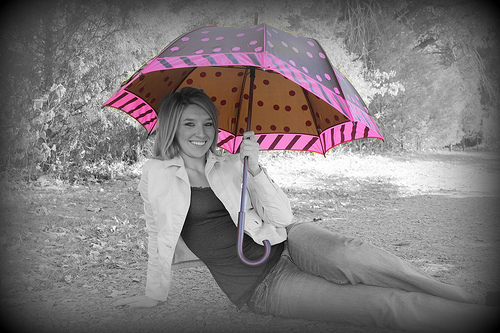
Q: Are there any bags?
A: No, there are no bags.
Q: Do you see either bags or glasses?
A: No, there are no bags or glasses.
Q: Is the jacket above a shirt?
A: Yes, the jacket is above a shirt.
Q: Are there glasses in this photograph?
A: No, there are no glasses.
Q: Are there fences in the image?
A: No, there are no fences.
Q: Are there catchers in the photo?
A: No, there are no catchers.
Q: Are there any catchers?
A: No, there are no catchers.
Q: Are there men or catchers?
A: No, there are no catchers or men.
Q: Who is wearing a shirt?
A: The girl is wearing a shirt.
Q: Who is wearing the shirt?
A: The girl is wearing a shirt.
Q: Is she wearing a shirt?
A: Yes, the girl is wearing a shirt.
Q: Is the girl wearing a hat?
A: No, the girl is wearing a shirt.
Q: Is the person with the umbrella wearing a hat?
A: No, the girl is wearing a shirt.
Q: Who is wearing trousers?
A: The girl is wearing trousers.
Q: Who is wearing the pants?
A: The girl is wearing trousers.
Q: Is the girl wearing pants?
A: Yes, the girl is wearing pants.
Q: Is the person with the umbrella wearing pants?
A: Yes, the girl is wearing pants.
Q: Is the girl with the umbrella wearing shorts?
A: No, the girl is wearing pants.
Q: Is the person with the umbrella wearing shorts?
A: No, the girl is wearing pants.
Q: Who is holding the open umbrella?
A: The girl is holding the umbrella.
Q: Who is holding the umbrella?
A: The girl is holding the umbrella.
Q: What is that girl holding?
A: The girl is holding the umbrella.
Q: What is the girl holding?
A: The girl is holding the umbrella.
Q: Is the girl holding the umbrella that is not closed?
A: Yes, the girl is holding the umbrella.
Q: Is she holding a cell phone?
A: No, the girl is holding the umbrella.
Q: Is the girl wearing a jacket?
A: Yes, the girl is wearing a jacket.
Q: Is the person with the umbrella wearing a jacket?
A: Yes, the girl is wearing a jacket.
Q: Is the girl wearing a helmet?
A: No, the girl is wearing a jacket.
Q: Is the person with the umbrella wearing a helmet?
A: No, the girl is wearing a jacket.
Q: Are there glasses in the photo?
A: No, there are no glasses.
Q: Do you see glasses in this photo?
A: No, there are no glasses.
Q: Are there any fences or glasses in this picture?
A: No, there are no glasses or fences.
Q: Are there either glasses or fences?
A: No, there are no glasses or fences.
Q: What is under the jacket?
A: The shirt is under the jacket.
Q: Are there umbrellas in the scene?
A: Yes, there is an umbrella.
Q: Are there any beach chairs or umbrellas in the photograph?
A: Yes, there is an umbrella.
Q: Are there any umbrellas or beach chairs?
A: Yes, there is an umbrella.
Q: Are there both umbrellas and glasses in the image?
A: No, there is an umbrella but no glasses.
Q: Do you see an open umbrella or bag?
A: Yes, there is an open umbrella.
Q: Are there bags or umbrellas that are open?
A: Yes, the umbrella is open.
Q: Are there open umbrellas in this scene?
A: Yes, there is an open umbrella.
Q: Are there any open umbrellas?
A: Yes, there is an open umbrella.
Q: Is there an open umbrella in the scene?
A: Yes, there is an open umbrella.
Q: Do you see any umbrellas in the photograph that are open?
A: Yes, there is an umbrella that is open.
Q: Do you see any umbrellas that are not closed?
A: Yes, there is a open umbrella.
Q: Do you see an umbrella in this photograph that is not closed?
A: Yes, there is a open umbrella.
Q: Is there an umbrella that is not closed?
A: Yes, there is a open umbrella.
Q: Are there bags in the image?
A: No, there are no bags.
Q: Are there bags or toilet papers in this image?
A: No, there are no bags or toilet papers.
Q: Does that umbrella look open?
A: Yes, the umbrella is open.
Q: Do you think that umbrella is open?
A: Yes, the umbrella is open.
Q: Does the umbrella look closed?
A: No, the umbrella is open.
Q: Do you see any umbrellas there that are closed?
A: No, there is an umbrella but it is open.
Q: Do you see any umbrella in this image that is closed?
A: No, there is an umbrella but it is open.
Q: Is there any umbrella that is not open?
A: No, there is an umbrella but it is open.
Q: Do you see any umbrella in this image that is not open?
A: No, there is an umbrella but it is open.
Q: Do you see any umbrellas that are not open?
A: No, there is an umbrella but it is open.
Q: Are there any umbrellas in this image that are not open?
A: No, there is an umbrella but it is open.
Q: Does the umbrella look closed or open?
A: The umbrella is open.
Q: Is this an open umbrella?
A: Yes, this is an open umbrella.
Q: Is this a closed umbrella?
A: No, this is an open umbrella.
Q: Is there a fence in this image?
A: No, there are no fences.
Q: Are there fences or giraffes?
A: No, there are no fences or giraffes.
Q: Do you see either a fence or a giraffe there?
A: No, there are no fences or giraffes.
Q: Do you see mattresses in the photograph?
A: No, there are no mattresses.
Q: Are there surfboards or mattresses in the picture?
A: No, there are no mattresses or surfboards.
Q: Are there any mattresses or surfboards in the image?
A: No, there are no mattresses or surfboards.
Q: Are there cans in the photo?
A: No, there are no cans.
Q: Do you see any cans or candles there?
A: No, there are no cans or candles.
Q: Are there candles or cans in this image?
A: No, there are no cans or candles.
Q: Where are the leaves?
A: The leaves are on the ground.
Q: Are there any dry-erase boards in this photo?
A: No, there are no dry-erase boards.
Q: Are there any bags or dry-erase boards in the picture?
A: No, there are no dry-erase boards or bags.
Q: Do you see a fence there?
A: No, there are no fences.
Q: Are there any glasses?
A: No, there are no glasses.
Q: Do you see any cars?
A: No, there are no cars.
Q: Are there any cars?
A: No, there are no cars.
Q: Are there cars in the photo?
A: No, there are no cars.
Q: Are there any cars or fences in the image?
A: No, there are no cars or fences.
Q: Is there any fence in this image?
A: No, there are no fences.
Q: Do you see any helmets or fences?
A: No, there are no fences or helmets.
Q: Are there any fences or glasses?
A: No, there are no glasses or fences.